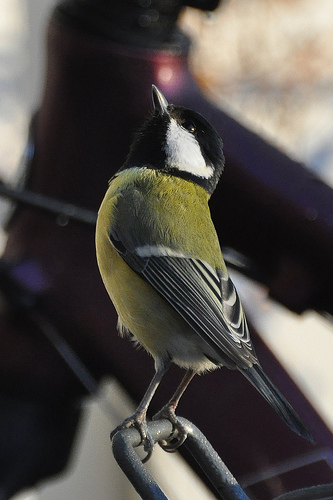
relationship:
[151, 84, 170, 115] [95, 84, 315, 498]
beak on bird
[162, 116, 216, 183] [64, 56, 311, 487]
cheek feathers on bird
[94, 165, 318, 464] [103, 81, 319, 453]
feathers on bird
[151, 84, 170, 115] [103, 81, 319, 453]
beak on bird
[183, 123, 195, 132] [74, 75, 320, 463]
eye on bird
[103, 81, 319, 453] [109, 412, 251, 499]
bird on wire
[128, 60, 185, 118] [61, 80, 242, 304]
mouth of bird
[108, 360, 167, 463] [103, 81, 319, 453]
leg of bird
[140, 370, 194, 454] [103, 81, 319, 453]
leg of bird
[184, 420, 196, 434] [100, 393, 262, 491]
light on stand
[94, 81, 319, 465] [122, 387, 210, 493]
bird on handle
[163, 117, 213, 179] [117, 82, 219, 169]
spot on face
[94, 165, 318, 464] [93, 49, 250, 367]
feathers sticking out from bird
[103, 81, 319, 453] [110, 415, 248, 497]
bird standing on metal hook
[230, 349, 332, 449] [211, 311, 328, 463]
bird tail has feathers